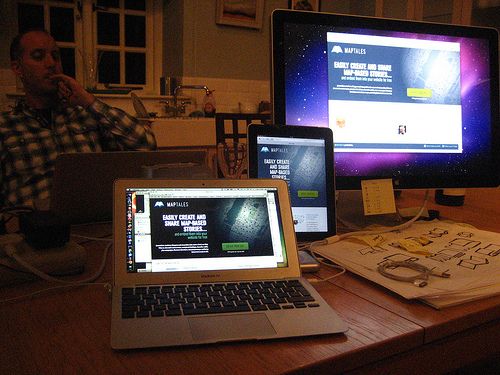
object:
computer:
[246, 122, 339, 244]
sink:
[142, 115, 216, 146]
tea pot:
[236, 100, 250, 113]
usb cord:
[377, 259, 432, 288]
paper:
[307, 214, 500, 310]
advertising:
[326, 30, 464, 156]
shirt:
[0, 95, 161, 213]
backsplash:
[214, 80, 258, 114]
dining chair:
[214, 113, 257, 178]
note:
[358, 176, 399, 217]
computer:
[268, 7, 500, 191]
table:
[0, 188, 500, 373]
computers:
[108, 175, 351, 352]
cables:
[374, 251, 455, 290]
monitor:
[266, 8, 500, 189]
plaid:
[31, 155, 47, 167]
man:
[0, 22, 160, 219]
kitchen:
[3, 0, 267, 148]